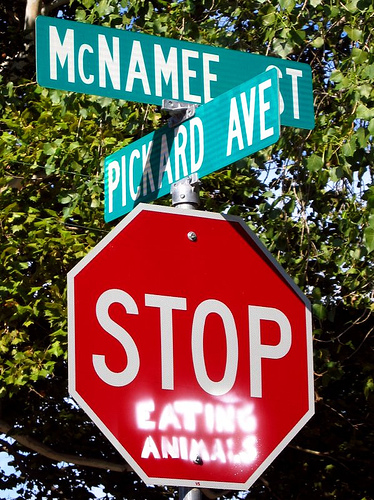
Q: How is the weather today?
A: It is clear.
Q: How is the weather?
A: It is clear.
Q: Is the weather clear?
A: Yes, it is clear.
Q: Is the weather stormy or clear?
A: It is clear.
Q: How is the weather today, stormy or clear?
A: It is clear.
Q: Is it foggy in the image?
A: No, it is clear.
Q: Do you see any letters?
A: Yes, there are letters.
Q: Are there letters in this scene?
A: Yes, there are letters.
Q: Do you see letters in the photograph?
A: Yes, there are letters.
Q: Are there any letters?
A: Yes, there are letters.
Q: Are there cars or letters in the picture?
A: Yes, there are letters.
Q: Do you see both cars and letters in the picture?
A: No, there are letters but no cars.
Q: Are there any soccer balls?
A: No, there are no soccer balls.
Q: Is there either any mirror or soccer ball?
A: No, there are no soccer balls or mirrors.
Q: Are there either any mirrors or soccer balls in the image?
A: No, there are no soccer balls or mirrors.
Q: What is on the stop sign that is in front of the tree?
A: The letters are on the stop sign.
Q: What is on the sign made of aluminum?
A: The letters are on the stop sign.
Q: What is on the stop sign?
A: The letters are on the stop sign.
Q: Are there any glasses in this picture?
A: No, there are no glasses.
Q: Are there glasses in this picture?
A: No, there are no glasses.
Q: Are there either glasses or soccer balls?
A: No, there are no glasses or soccer balls.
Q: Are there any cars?
A: No, there are no cars.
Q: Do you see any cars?
A: No, there are no cars.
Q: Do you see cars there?
A: No, there are no cars.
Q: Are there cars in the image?
A: No, there are no cars.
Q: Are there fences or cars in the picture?
A: No, there are no cars or fences.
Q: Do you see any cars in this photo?
A: No, there are no cars.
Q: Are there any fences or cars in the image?
A: No, there are no cars or fences.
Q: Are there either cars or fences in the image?
A: No, there are no cars or fences.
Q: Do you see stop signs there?
A: Yes, there is a stop sign.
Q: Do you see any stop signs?
A: Yes, there is a stop sign.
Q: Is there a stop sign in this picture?
A: Yes, there is a stop sign.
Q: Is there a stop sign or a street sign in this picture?
A: Yes, there is a stop sign.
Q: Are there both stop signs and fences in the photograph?
A: No, there is a stop sign but no fences.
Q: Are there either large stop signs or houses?
A: Yes, there is a large stop sign.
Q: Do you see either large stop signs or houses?
A: Yes, there is a large stop sign.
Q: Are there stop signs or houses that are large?
A: Yes, the stop sign is large.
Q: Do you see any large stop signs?
A: Yes, there is a large stop sign.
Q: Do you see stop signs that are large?
A: Yes, there is a large stop sign.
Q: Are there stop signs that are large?
A: Yes, there is a stop sign that is large.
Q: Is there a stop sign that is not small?
A: Yes, there is a large stop sign.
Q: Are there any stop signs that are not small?
A: Yes, there is a large stop sign.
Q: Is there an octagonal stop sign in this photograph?
A: Yes, there is an octagonal stop sign.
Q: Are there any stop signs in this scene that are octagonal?
A: Yes, there is a stop sign that is octagonal.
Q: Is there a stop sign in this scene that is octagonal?
A: Yes, there is a stop sign that is octagonal.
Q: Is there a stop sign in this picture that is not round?
A: Yes, there is a octagonal stop sign.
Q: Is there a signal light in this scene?
A: No, there are no traffic lights.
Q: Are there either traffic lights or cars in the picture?
A: No, there are no traffic lights or cars.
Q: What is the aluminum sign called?
A: The sign is a stop sign.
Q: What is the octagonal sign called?
A: The sign is a stop sign.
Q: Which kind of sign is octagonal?
A: The sign is a stop sign.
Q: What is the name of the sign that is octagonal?
A: The sign is a stop sign.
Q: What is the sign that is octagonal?
A: The sign is a stop sign.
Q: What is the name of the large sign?
A: The sign is a stop sign.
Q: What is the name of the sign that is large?
A: The sign is a stop sign.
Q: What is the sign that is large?
A: The sign is a stop sign.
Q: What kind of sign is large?
A: The sign is a stop sign.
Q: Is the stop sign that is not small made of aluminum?
A: Yes, the stop sign is made of aluminum.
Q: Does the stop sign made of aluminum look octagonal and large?
A: Yes, the stop sign is octagonal and large.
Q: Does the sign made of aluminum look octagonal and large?
A: Yes, the stop sign is octagonal and large.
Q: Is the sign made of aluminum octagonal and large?
A: Yes, the stop sign is octagonal and large.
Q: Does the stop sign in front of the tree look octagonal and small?
A: No, the stop sign is octagonal but large.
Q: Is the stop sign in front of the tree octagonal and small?
A: No, the stop sign is octagonal but large.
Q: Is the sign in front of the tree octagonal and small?
A: No, the stop sign is octagonal but large.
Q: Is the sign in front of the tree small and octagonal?
A: No, the stop sign is octagonal but large.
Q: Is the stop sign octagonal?
A: Yes, the stop sign is octagonal.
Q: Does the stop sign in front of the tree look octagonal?
A: Yes, the stop sign is octagonal.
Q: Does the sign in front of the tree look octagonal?
A: Yes, the stop sign is octagonal.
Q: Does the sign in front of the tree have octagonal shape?
A: Yes, the stop sign is octagonal.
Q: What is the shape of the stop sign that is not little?
A: The stop sign is octagonal.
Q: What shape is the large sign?
A: The stop sign is octagonal.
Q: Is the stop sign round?
A: No, the stop sign is octagonal.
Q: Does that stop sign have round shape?
A: No, the stop sign is octagonal.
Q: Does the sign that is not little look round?
A: No, the stop sign is octagonal.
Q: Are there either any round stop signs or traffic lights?
A: No, there is a stop sign but it is octagonal.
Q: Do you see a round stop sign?
A: No, there is a stop sign but it is octagonal.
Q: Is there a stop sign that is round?
A: No, there is a stop sign but it is octagonal.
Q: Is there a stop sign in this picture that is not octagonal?
A: No, there is a stop sign but it is octagonal.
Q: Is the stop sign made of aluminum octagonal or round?
A: The stop sign is octagonal.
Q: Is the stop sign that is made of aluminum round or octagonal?
A: The stop sign is octagonal.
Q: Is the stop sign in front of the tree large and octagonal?
A: Yes, the stop sign is large and octagonal.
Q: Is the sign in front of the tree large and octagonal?
A: Yes, the stop sign is large and octagonal.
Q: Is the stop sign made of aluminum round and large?
A: No, the stop sign is large but octagonal.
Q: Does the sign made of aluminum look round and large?
A: No, the stop sign is large but octagonal.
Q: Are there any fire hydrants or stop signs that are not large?
A: No, there is a stop sign but it is large.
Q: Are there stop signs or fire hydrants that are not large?
A: No, there is a stop sign but it is large.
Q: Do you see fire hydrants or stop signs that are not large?
A: No, there is a stop sign but it is large.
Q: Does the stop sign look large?
A: Yes, the stop sign is large.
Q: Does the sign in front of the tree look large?
A: Yes, the stop sign is large.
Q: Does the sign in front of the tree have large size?
A: Yes, the stop sign is large.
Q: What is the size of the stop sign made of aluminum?
A: The stop sign is large.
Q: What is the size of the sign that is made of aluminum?
A: The stop sign is large.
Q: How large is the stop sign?
A: The stop sign is large.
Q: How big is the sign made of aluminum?
A: The stop sign is large.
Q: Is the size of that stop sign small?
A: No, the stop sign is large.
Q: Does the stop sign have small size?
A: No, the stop sign is large.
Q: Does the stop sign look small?
A: No, the stop sign is large.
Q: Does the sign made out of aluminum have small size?
A: No, the stop sign is large.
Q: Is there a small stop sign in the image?
A: No, there is a stop sign but it is large.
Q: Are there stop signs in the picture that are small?
A: No, there is a stop sign but it is large.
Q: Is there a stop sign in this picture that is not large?
A: No, there is a stop sign but it is large.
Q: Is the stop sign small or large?
A: The stop sign is large.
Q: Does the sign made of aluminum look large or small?
A: The stop sign is large.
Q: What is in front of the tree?
A: The stop sign is in front of the tree.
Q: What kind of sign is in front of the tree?
A: The sign is a stop sign.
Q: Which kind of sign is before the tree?
A: The sign is a stop sign.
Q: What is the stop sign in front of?
A: The stop sign is in front of the tree.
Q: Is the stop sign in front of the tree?
A: Yes, the stop sign is in front of the tree.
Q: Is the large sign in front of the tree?
A: Yes, the stop sign is in front of the tree.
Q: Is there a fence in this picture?
A: No, there are no fences.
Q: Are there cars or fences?
A: No, there are no fences or cars.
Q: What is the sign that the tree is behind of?
A: The sign is a stop sign.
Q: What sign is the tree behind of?
A: The tree is behind the stop sign.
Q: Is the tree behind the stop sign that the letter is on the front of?
A: Yes, the tree is behind the stop sign.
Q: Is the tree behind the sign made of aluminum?
A: Yes, the tree is behind the stop sign.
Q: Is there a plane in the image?
A: No, there are no airplanes.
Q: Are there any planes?
A: No, there are no planes.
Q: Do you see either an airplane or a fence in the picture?
A: No, there are no airplanes or fences.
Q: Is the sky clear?
A: Yes, the sky is clear.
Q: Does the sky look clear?
A: Yes, the sky is clear.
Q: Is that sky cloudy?
A: No, the sky is clear.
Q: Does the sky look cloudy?
A: No, the sky is clear.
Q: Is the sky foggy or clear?
A: The sky is clear.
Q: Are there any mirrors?
A: No, there are no mirrors.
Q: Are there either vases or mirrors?
A: No, there are no mirrors or vases.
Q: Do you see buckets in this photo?
A: No, there are no buckets.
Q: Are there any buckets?
A: No, there are no buckets.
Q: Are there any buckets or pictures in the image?
A: No, there are no buckets or pictures.